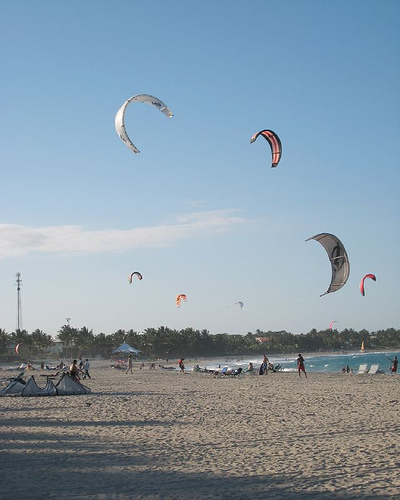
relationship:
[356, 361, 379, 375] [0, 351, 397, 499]
chairs in sand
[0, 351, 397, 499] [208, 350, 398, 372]
sand by water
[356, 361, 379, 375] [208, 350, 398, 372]
chairs by water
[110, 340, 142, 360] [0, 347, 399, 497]
tent on beach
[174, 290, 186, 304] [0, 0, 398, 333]
kite flying sky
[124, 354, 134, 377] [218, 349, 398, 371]
person walking towards water